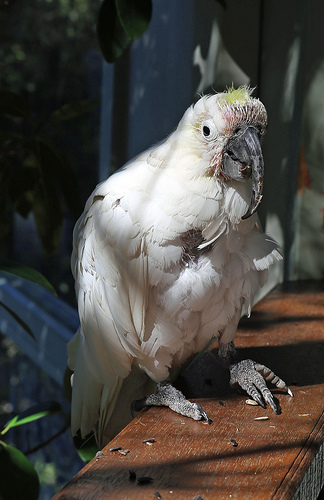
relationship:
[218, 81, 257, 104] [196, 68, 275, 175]
tuft of feathers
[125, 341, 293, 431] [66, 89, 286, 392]
feet of bird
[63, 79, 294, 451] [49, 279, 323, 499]
bird on platform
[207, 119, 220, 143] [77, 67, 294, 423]
eye of bird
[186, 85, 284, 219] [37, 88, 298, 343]
face of bird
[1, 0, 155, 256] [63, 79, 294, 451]
leaves behind bird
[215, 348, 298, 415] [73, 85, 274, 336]
foot of bird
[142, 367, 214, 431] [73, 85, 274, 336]
feet of bird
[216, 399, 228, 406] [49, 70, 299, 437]
seed near bird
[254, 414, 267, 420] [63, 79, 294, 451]
seed near bird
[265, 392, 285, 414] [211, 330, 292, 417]
nail on foot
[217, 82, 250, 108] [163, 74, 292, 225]
feathers on top of bird's head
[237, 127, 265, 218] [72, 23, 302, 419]
beak of parrot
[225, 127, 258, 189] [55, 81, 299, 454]
beak of parrot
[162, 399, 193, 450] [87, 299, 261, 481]
right leg of parrot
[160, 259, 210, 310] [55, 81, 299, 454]
bald part on breast of parrot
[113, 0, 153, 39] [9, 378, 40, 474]
leaf hanging down